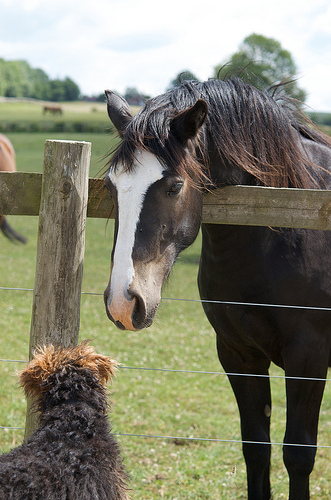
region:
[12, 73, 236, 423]
The horse is examining the dog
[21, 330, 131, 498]
The dog is shaggy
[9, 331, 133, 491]
The dog has brown and black fur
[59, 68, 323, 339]
The horse is black and white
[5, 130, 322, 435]
The horse looks over the fence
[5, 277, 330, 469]
The fence has metal wires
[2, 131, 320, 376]
The fence is made of wood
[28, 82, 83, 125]
Another horse is in the distance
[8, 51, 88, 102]
Trees are in the distance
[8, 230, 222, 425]
The grass is green on the other side of the fence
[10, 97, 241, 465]
horse looking at the dog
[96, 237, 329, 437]
fence has wires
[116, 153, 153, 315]
horse has a white stripe down his nose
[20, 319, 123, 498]
dog next to the pole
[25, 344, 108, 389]
dog has brown ears and top of his head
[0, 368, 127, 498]
dog's body is black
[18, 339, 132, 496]
black is shaggy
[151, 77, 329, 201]
horse's man is black and brown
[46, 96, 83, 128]
horse in the back field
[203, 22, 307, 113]
tree behind the horse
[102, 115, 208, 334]
horse with white stripe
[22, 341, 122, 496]
small wire haired dog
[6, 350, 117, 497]
black and brown dog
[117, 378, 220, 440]
green grass on the ground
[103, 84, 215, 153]
ears of a horse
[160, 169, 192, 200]
eye of a horse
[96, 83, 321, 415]
horse behind a fence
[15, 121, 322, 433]
wooden brown fence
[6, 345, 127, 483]
dog in front of fence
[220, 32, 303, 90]
tree with green leaves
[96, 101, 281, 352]
Horse with a white face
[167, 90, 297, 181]
Horse with with long hair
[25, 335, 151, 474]
Dog in front of a horse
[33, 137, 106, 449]
Wooden post in the ground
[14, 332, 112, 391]
dog with brown fur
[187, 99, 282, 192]
horse with long hair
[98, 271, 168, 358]
Horse with a pink nose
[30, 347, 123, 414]
dog looking at a horse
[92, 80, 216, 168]
Horse with its ears perked up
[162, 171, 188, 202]
horse with black eyes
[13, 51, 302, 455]
close-up of two animals meeting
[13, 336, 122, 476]
a fuzzy headed dog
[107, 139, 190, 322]
a horse's long face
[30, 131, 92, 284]
wooden post of the fence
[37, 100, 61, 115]
horse in the distance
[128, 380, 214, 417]
short grass of the pasture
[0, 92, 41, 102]
section of white fence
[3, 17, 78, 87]
green trees and blue sky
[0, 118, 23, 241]
animal's hind quarters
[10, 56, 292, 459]
curious horse looks down at a curious dog